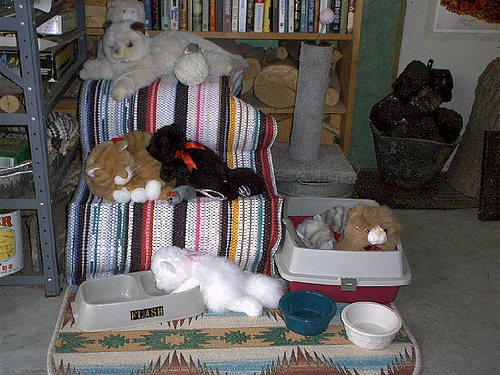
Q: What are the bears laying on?
A: Chair.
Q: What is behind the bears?
A: Bookshelf.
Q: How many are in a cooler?
A: One.